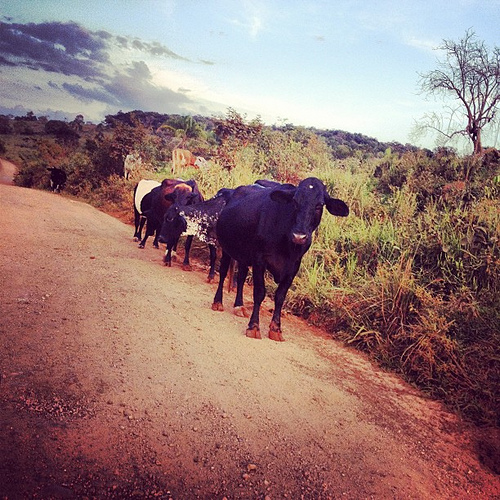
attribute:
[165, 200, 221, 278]
cow — black, white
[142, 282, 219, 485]
road — brown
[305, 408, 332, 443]
road — brown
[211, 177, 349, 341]
cow — black, standing, white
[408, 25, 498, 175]
tree — leafless, brown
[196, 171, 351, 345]
cow — white, black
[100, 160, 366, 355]
cows — domestic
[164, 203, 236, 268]
cow — black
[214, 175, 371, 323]
cow — black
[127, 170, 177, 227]
cow — white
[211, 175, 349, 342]
cows — standing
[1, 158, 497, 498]
road — brown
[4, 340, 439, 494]
road — dirt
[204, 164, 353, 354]
cow — standing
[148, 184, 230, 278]
cow — standing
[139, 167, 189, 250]
cow — standing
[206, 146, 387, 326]
cow — black, white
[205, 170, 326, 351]
cow — white, black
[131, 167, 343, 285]
cow — black and white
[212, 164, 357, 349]
cow — black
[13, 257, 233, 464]
road — brown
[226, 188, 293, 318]
cow — black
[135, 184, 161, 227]
cow — white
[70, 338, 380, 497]
road — brown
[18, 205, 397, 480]
road — brown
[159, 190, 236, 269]
cow — black and white